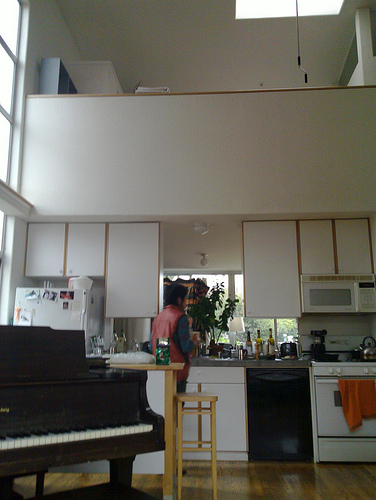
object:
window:
[275, 318, 298, 362]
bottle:
[266, 324, 275, 359]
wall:
[16, 86, 374, 223]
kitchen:
[12, 214, 376, 473]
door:
[102, 221, 158, 322]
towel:
[337, 375, 363, 433]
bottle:
[153, 335, 171, 366]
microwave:
[298, 271, 375, 317]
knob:
[335, 364, 342, 379]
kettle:
[357, 334, 376, 364]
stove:
[310, 348, 375, 379]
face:
[181, 284, 189, 309]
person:
[149, 281, 200, 478]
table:
[106, 361, 186, 500]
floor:
[0, 458, 375, 498]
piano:
[0, 322, 165, 499]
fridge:
[12, 284, 105, 357]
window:
[0, 40, 18, 118]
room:
[0, 0, 375, 498]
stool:
[173, 392, 220, 498]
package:
[154, 337, 172, 366]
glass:
[107, 342, 115, 356]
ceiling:
[50, 0, 375, 97]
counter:
[93, 354, 312, 467]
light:
[234, 0, 343, 21]